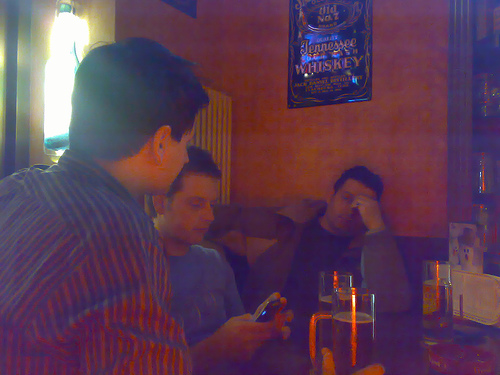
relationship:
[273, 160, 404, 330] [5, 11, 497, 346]
man at pub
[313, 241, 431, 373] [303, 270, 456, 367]
glasses of beer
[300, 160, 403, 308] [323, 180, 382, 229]
man touching face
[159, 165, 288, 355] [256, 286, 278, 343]
man looking at cellphone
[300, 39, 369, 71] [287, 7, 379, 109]
tennessee whiskey on sign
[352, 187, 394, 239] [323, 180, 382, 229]
hand on face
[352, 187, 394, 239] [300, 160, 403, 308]
hand of man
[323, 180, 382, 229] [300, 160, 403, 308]
face of man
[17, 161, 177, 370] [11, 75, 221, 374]
shirt of man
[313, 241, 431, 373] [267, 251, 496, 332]
glasses on table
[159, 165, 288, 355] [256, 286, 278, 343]
man on cellphone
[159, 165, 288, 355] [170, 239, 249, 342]
man in shirt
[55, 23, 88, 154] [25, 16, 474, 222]
light on wall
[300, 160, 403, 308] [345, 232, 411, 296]
man in jacket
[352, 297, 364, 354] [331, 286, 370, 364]
light on mug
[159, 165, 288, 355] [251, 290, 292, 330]
man using phone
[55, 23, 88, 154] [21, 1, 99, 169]
light coming through window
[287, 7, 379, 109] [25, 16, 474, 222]
sign on wall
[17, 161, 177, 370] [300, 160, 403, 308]
shirt on man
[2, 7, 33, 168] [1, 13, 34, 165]
frame of door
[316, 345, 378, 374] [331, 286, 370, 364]
hand grasping mug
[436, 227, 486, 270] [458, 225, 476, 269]
picture of snowman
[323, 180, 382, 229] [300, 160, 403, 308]
head of man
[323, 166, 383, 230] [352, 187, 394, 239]
head on hand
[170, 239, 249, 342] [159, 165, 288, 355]
shirt on man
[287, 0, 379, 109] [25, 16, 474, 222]
sign on wall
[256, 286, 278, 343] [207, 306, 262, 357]
cellphone in hand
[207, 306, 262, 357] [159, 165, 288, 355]
hand of man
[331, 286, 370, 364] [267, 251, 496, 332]
mug on table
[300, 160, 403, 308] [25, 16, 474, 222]
man against wall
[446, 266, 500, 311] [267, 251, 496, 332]
menus on table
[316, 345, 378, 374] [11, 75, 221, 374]
hand of man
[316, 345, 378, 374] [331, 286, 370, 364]
hand on mug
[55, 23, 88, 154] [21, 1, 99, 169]
light in window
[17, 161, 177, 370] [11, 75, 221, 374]
stripes of man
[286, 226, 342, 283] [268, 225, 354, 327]
shirt on torso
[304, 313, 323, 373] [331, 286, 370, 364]
handle of mug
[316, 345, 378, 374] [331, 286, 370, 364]
hand holding mug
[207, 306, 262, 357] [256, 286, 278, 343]
hand holding cellphone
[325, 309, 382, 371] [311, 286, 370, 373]
liquid in mug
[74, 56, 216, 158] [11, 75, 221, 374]
hair of man